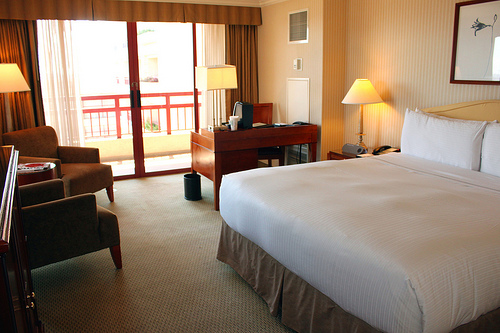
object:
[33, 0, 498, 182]
background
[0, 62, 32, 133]
lamp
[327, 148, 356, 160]
night stand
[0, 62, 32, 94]
lamp shade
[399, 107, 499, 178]
pillow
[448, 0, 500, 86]
picture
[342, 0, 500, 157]
wall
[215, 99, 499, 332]
bed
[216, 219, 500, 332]
bed skirt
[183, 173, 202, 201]
trash can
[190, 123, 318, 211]
desk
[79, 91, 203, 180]
balcony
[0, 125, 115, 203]
chair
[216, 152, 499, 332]
sheet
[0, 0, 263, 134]
curtains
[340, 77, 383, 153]
lamps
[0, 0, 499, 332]
room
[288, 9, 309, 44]
vent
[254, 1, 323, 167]
wall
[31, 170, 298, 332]
carpet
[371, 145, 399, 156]
phone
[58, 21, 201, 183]
door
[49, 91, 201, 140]
railing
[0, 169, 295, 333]
floor